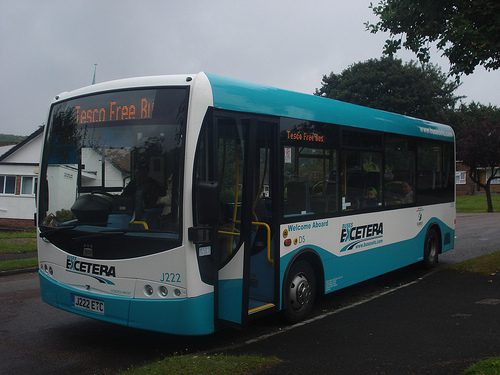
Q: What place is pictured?
A: It is a street.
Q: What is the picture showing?
A: It is showing a street.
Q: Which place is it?
A: It is a street.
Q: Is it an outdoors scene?
A: Yes, it is outdoors.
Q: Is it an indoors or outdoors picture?
A: It is outdoors.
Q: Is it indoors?
A: No, it is outdoors.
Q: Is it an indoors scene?
A: No, it is outdoors.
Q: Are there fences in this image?
A: No, there are no fences.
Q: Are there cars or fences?
A: No, there are no fences or cars.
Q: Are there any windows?
A: Yes, there are windows.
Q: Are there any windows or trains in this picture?
A: Yes, there are windows.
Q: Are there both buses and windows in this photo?
A: Yes, there are both windows and a bus.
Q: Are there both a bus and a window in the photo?
A: Yes, there are both a window and a bus.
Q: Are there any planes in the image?
A: No, there are no planes.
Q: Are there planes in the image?
A: No, there are no planes.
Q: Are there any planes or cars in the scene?
A: No, there are no planes or cars.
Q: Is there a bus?
A: Yes, there is a bus.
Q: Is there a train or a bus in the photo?
A: Yes, there is a bus.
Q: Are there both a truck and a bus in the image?
A: No, there is a bus but no trucks.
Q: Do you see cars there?
A: No, there are no cars.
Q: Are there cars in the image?
A: No, there are no cars.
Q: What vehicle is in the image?
A: The vehicle is a bus.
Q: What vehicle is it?
A: The vehicle is a bus.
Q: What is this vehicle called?
A: That is a bus.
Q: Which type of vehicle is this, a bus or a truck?
A: That is a bus.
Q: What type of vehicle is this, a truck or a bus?
A: That is a bus.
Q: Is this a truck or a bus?
A: This is a bus.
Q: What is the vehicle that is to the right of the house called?
A: The vehicle is a bus.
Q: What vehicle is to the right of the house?
A: The vehicle is a bus.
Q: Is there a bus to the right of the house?
A: Yes, there is a bus to the right of the house.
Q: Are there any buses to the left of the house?
A: No, the bus is to the right of the house.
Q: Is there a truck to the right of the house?
A: No, there is a bus to the right of the house.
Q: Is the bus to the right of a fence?
A: No, the bus is to the right of the house.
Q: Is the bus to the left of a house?
A: No, the bus is to the right of a house.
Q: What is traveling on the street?
A: The bus is traveling on the street.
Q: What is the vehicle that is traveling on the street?
A: The vehicle is a bus.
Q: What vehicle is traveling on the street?
A: The vehicle is a bus.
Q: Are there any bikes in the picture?
A: No, there are no bikes.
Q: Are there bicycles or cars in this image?
A: No, there are no bicycles or cars.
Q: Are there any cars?
A: No, there are no cars.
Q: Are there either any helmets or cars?
A: No, there are no cars or helmets.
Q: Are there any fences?
A: No, there are no fences.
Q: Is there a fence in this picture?
A: No, there are no fences.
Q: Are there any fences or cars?
A: No, there are no fences or cars.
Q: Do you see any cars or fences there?
A: No, there are no fences or cars.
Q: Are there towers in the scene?
A: No, there are no towers.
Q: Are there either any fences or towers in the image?
A: No, there are no towers or fences.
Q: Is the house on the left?
A: Yes, the house is on the left of the image.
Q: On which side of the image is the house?
A: The house is on the left of the image.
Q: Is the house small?
A: Yes, the house is small.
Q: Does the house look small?
A: Yes, the house is small.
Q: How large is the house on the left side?
A: The house is small.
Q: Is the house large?
A: No, the house is small.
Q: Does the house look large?
A: No, the house is small.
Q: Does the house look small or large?
A: The house is small.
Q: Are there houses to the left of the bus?
A: Yes, there is a house to the left of the bus.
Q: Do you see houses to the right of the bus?
A: No, the house is to the left of the bus.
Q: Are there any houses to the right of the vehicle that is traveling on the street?
A: No, the house is to the left of the bus.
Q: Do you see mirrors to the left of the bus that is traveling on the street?
A: No, there is a house to the left of the bus.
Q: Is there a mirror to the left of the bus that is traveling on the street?
A: No, there is a house to the left of the bus.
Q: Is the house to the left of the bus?
A: Yes, the house is to the left of the bus.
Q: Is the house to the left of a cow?
A: No, the house is to the left of the bus.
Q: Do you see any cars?
A: No, there are no cars.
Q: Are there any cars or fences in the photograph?
A: No, there are no cars or fences.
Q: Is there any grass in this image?
A: Yes, there is grass.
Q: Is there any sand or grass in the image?
A: Yes, there is grass.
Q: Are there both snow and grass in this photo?
A: No, there is grass but no snow.